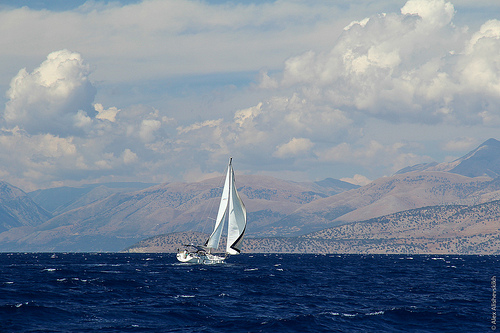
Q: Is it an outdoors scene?
A: Yes, it is outdoors.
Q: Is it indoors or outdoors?
A: It is outdoors.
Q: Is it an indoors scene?
A: No, it is outdoors.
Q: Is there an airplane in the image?
A: No, there are no airplanes.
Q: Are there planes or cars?
A: No, there are no planes or cars.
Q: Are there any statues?
A: No, there are no statues.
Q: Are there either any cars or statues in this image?
A: No, there are no statues or cars.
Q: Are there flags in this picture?
A: No, there are no flags.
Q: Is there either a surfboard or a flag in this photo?
A: No, there are no flags or surfboards.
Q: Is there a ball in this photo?
A: No, there are no balls.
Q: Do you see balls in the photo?
A: No, there are no balls.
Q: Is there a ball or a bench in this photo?
A: No, there are no balls or benches.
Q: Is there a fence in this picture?
A: No, there are no fences.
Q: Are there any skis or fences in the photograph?
A: No, there are no fences or skis.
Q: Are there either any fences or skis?
A: No, there are no fences or skis.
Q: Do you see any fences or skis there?
A: No, there are no fences or skis.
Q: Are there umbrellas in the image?
A: No, there are no umbrellas.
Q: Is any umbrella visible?
A: No, there are no umbrellas.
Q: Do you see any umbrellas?
A: No, there are no umbrellas.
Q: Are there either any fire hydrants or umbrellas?
A: No, there are no umbrellas or fire hydrants.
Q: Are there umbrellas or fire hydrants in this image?
A: No, there are no umbrellas or fire hydrants.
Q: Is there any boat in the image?
A: Yes, there is a boat.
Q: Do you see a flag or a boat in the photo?
A: Yes, there is a boat.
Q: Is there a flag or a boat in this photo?
A: Yes, there is a boat.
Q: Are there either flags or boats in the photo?
A: Yes, there is a boat.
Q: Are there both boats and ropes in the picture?
A: No, there is a boat but no ropes.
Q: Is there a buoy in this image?
A: No, there are no buoys.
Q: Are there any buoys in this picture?
A: No, there are no buoys.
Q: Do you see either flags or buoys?
A: No, there are no buoys or flags.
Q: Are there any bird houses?
A: No, there are no bird houses.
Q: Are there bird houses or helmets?
A: No, there are no bird houses or helmets.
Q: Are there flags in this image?
A: No, there are no flags.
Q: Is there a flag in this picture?
A: No, there are no flags.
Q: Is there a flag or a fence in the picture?
A: No, there are no flags or fences.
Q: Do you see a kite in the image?
A: No, there are no kites.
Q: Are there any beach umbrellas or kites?
A: No, there are no kites or beach umbrellas.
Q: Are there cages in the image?
A: No, there are no cages.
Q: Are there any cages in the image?
A: No, there are no cages.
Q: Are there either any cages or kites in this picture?
A: No, there are no cages or kites.